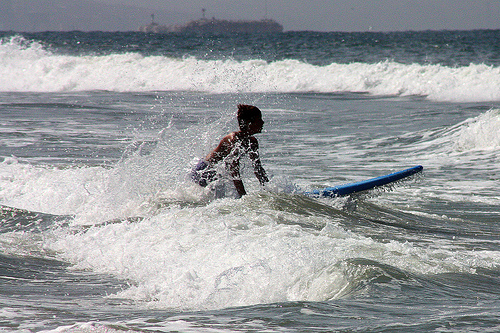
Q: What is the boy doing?
A: Surfing.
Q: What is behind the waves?
A: Choppy blue waters.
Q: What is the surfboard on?
A: Waves.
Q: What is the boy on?
A: Surfboard.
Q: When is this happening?
A: During the day time.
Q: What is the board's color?
A: Blue.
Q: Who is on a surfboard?
A: A man.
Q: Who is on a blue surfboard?
A: A man.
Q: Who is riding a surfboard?
A: A man.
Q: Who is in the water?
A: A man.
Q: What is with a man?
A: A surfboard.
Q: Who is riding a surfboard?
A: A man.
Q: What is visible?
A: Water.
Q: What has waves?
A: Water.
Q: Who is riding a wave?
A: A surfer.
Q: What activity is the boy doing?
A: Surfing.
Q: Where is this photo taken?
A: In the water.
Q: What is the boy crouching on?
A: A surfboard.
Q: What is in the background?
A: A building.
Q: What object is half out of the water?
A: Surfboard.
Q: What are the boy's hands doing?
A: Holding on to the surfboard.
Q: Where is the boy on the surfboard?
A: Near the back.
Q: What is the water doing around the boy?
A: Splashing.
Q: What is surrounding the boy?
A: Water.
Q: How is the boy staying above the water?
A: The surfboard is buoyant.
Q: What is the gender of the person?
A: Male.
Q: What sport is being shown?
A: Surfing.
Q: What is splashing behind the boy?
A: Water.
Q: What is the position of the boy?
A: Kneeling.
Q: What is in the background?
A: Ship.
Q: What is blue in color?
A: Surfboard.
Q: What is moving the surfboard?
A: Waves.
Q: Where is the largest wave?
A: Between the male and the ship.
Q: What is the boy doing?
A: Surfing.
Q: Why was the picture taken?
A: To capture the boy surfing.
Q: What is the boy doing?
A: Surfing.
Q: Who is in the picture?
A: A boy.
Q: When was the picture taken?
A: During the day.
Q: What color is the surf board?
A: Blue.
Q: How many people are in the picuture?
A: One.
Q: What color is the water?
A: Blue.